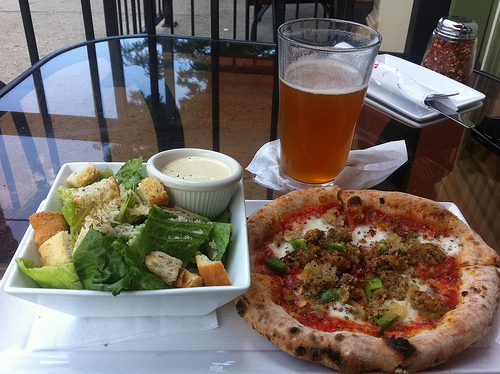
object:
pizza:
[239, 185, 499, 370]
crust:
[264, 334, 480, 373]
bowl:
[2, 161, 249, 317]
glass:
[277, 18, 380, 186]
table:
[0, 33, 499, 371]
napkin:
[246, 138, 408, 190]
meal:
[0, 146, 499, 373]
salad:
[23, 161, 234, 290]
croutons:
[68, 173, 126, 217]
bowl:
[144, 148, 241, 216]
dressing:
[161, 157, 228, 179]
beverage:
[279, 64, 365, 180]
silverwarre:
[429, 95, 477, 129]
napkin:
[371, 58, 443, 103]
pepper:
[365, 277, 383, 299]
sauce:
[425, 264, 459, 300]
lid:
[436, 17, 479, 41]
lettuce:
[17, 260, 86, 290]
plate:
[2, 199, 499, 372]